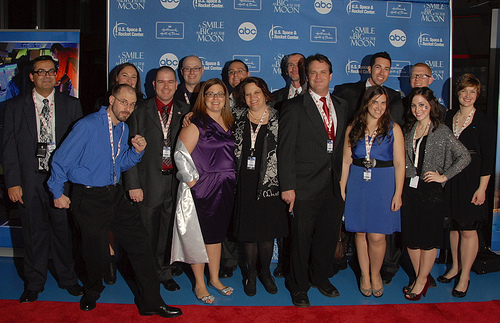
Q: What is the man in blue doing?
A: Curling his arm.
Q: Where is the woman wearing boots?
A: Standing in the middle.